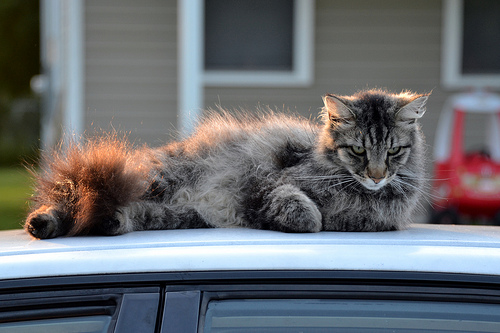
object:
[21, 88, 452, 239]
cat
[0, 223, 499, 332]
car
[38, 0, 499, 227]
house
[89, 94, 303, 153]
long fur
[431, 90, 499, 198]
toy car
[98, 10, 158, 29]
tan siding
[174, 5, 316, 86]
window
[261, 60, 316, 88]
white frame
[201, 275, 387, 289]
window seal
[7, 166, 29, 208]
lawn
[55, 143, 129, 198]
tail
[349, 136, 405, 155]
eyes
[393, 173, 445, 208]
long whiskers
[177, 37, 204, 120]
white trim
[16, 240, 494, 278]
roof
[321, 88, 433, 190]
head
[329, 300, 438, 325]
window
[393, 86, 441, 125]
ear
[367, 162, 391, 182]
nose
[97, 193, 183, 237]
leg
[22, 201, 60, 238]
leg